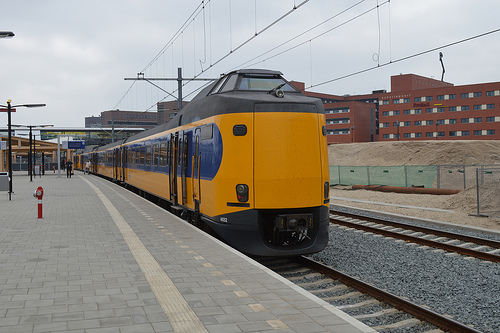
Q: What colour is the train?
A: Yellow.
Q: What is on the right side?
A: Buildings.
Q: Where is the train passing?
A: On a railway.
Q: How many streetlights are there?
A: Two.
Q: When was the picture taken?
A: Daytime.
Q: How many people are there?
A: Two.